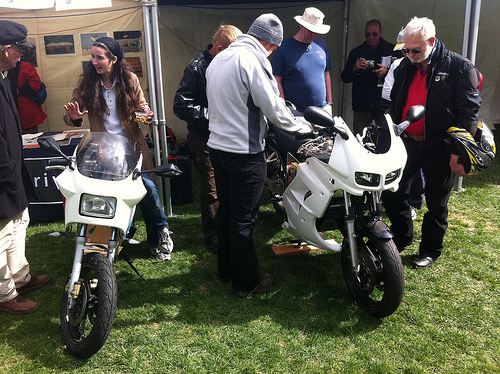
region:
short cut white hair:
[398, 17, 435, 42]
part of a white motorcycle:
[270, 94, 433, 311]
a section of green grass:
[144, 273, 391, 373]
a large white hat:
[292, 7, 333, 34]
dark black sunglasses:
[398, 40, 425, 55]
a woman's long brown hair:
[80, 55, 139, 122]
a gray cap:
[247, 12, 284, 44]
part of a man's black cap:
[0, 15, 38, 50]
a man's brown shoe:
[5, 286, 44, 313]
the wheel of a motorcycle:
[340, 220, 403, 314]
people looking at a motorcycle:
[171, 36, 477, 218]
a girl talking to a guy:
[2, 30, 125, 114]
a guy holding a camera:
[356, 52, 385, 80]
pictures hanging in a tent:
[48, 34, 88, 56]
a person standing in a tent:
[16, 68, 48, 136]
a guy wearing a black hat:
[1, 17, 29, 51]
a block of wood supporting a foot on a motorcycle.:
[268, 235, 325, 267]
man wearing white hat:
[303, 15, 321, 26]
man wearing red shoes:
[6, 298, 44, 313]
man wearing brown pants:
[202, 175, 213, 201]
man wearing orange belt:
[411, 130, 423, 143]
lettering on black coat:
[434, 69, 448, 86]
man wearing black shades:
[398, 46, 425, 53]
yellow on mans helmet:
[450, 125, 460, 132]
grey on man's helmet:
[478, 150, 488, 157]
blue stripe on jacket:
[246, 115, 256, 150]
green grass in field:
[205, 325, 240, 352]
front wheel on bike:
[341, 220, 416, 320]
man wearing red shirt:
[410, 87, 420, 98]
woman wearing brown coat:
[90, 115, 100, 125]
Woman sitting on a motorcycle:
[68, 35, 185, 258]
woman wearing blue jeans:
[140, 167, 172, 226]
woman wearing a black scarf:
[92, 34, 131, 65]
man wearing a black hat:
[2, 16, 32, 49]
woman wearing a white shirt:
[95, 80, 125, 142]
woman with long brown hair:
[68, 53, 138, 120]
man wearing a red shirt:
[405, 70, 434, 142]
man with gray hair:
[390, 7, 440, 68]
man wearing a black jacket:
[386, 60, 476, 120]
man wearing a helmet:
[448, 111, 498, 180]